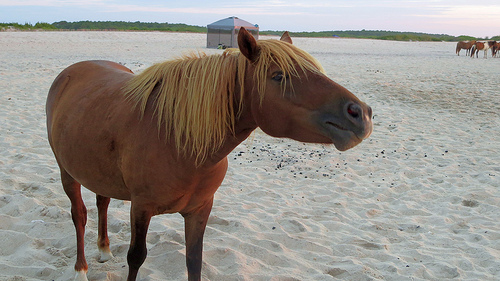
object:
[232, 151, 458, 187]
trash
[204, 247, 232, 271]
footprint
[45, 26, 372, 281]
pony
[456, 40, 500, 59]
horses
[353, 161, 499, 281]
sand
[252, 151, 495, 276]
footprints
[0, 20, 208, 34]
trees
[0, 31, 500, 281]
sand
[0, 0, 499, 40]
sky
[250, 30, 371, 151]
head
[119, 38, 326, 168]
mane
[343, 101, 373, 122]
nose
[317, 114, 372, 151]
mouth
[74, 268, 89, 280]
hair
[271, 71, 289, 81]
eye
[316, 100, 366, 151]
part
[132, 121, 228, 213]
chest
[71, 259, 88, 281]
feet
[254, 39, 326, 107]
hair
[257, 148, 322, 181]
specs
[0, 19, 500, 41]
hill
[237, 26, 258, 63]
ears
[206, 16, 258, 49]
center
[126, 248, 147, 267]
knee